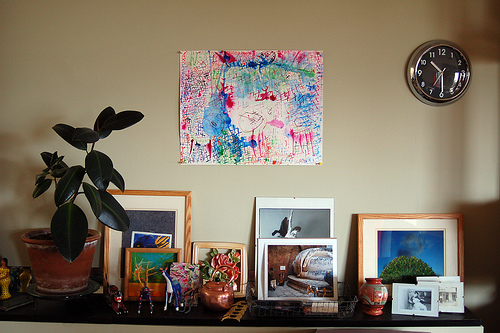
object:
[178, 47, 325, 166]
drawing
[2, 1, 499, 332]
wall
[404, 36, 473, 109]
clock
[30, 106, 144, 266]
plant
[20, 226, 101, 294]
pot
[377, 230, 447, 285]
photograph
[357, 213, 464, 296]
frame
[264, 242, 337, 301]
photograph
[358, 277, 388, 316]
vase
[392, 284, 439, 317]
photograph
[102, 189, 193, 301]
frame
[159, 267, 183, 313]
giraffe toy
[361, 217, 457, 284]
card stock matt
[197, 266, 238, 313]
tea pot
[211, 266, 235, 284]
handle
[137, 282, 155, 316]
animal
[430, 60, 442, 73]
clock hands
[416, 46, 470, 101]
clock face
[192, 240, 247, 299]
frame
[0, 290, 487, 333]
table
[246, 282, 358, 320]
wire basket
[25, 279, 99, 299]
dish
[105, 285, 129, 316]
animal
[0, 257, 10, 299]
woman figurine